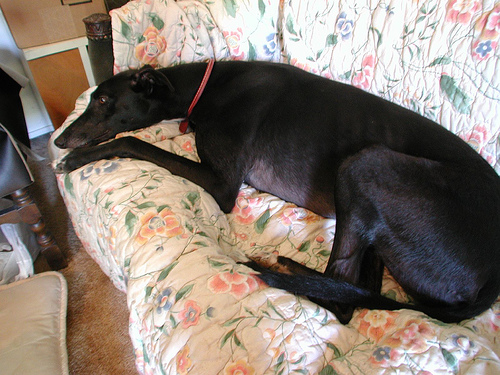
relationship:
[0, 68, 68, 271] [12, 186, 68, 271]
table has leg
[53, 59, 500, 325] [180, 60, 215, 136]
dog has collar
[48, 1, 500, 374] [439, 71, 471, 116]
couch has print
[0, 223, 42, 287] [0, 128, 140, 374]
bag on floor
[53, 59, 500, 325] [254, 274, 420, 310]
dog has tail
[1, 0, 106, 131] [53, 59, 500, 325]
wall behind dog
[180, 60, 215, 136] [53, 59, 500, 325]
collar on dog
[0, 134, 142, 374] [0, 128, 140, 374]
carpet on floor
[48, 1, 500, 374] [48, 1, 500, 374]
couch has couch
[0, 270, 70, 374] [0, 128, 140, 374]
cushion on floor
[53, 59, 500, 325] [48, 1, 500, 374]
dog resting on couch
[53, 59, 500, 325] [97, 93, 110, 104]
dog has eye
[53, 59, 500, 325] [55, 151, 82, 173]
dog has paw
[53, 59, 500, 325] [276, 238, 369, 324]
dog has leg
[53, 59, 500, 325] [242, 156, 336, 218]
dog has stomach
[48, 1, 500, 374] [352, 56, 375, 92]
couch has flower